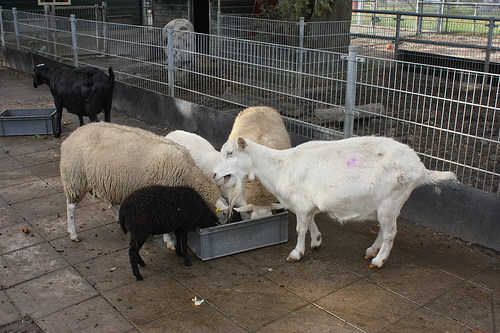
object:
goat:
[208, 133, 462, 270]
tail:
[425, 167, 463, 192]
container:
[183, 198, 296, 262]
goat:
[26, 55, 122, 139]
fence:
[1, 10, 499, 197]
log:
[310, 102, 385, 125]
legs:
[286, 213, 312, 264]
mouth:
[215, 173, 235, 190]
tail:
[107, 65, 117, 86]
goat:
[52, 119, 237, 243]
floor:
[1, 65, 499, 332]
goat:
[114, 180, 221, 283]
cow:
[150, 7, 209, 97]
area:
[351, 0, 499, 35]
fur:
[58, 120, 222, 211]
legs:
[177, 233, 194, 269]